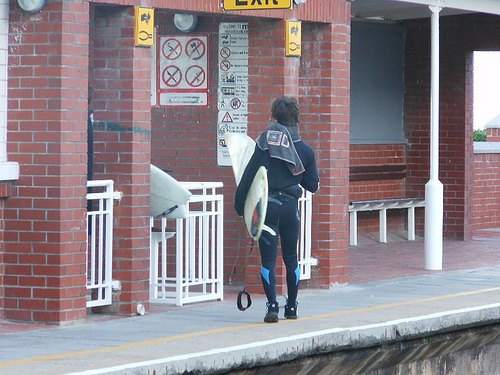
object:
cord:
[227, 214, 255, 313]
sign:
[215, 21, 250, 166]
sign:
[161, 64, 183, 87]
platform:
[0, 264, 500, 375]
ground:
[0, 259, 500, 375]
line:
[68, 301, 500, 374]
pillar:
[422, 4, 444, 273]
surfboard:
[221, 131, 278, 243]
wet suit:
[230, 119, 321, 307]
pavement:
[0, 262, 500, 375]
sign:
[161, 37, 183, 61]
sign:
[184, 64, 205, 87]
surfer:
[230, 93, 322, 325]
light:
[171, 12, 198, 34]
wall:
[0, 0, 354, 329]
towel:
[255, 121, 307, 177]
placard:
[155, 33, 210, 110]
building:
[0, 0, 500, 335]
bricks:
[32, 109, 69, 120]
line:
[0, 284, 500, 371]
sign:
[185, 37, 206, 60]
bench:
[347, 196, 425, 247]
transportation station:
[0, 0, 500, 375]